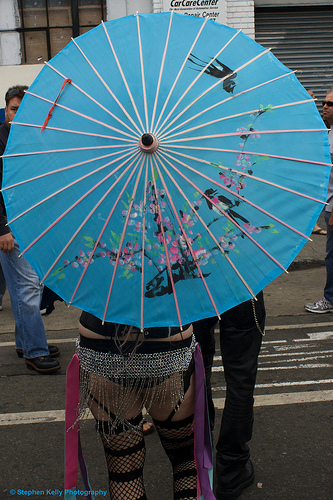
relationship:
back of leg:
[150, 383, 193, 455] [108, 441, 142, 496]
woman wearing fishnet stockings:
[64, 309, 225, 496] [111, 443, 191, 466]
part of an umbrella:
[164, 264, 234, 299] [0, 10, 332, 333]